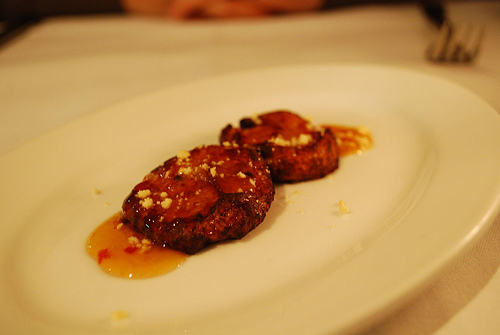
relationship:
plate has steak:
[1, 62, 499, 334] [121, 109, 339, 254]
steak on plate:
[121, 109, 339, 254] [1, 62, 499, 334]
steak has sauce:
[121, 109, 339, 254] [84, 107, 373, 282]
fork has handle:
[417, 0, 486, 64] [417, 0, 448, 25]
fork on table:
[417, 0, 486, 64] [1, 3, 499, 335]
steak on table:
[121, 109, 339, 254] [1, 3, 499, 335]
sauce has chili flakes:
[84, 107, 373, 282] [94, 108, 305, 263]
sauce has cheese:
[84, 107, 373, 282] [92, 114, 352, 241]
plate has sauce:
[1, 62, 499, 334] [84, 107, 373, 282]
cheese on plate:
[92, 114, 352, 241] [1, 62, 499, 334]